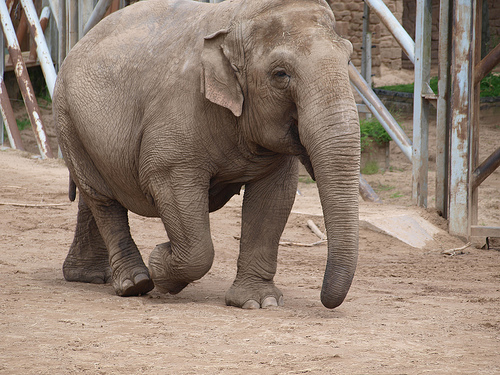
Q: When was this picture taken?
A: Daytime.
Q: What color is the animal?
A: Grey.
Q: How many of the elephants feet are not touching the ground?
A: 1.